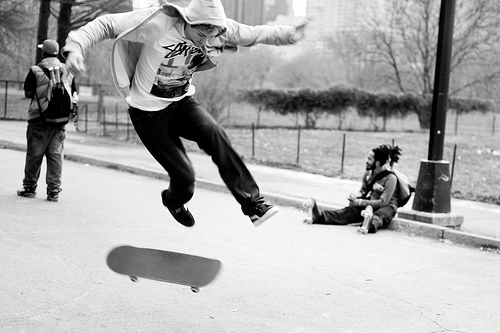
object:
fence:
[0, 80, 500, 205]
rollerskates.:
[303, 198, 374, 235]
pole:
[410, 0, 457, 212]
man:
[302, 144, 415, 235]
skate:
[302, 196, 321, 224]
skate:
[357, 204, 373, 235]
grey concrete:
[0, 146, 500, 333]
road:
[0, 146, 500, 333]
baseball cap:
[39, 39, 60, 55]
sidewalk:
[0, 120, 500, 242]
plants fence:
[239, 82, 499, 132]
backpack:
[34, 64, 71, 127]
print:
[149, 41, 206, 99]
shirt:
[120, 11, 207, 111]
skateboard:
[106, 245, 221, 293]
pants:
[127, 96, 266, 216]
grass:
[100, 126, 500, 204]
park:
[0, 0, 500, 333]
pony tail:
[380, 144, 401, 169]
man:
[60, 0, 313, 227]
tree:
[0, 0, 500, 132]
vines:
[239, 83, 497, 132]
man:
[16, 39, 79, 202]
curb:
[0, 142, 500, 333]